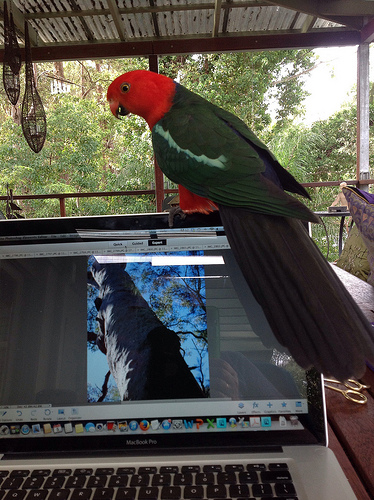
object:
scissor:
[323, 378, 368, 405]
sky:
[260, 41, 373, 135]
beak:
[110, 101, 122, 121]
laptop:
[0, 210, 359, 500]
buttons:
[174, 473, 193, 486]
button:
[229, 484, 249, 498]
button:
[206, 484, 226, 498]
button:
[253, 483, 271, 496]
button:
[275, 480, 297, 496]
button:
[216, 471, 236, 483]